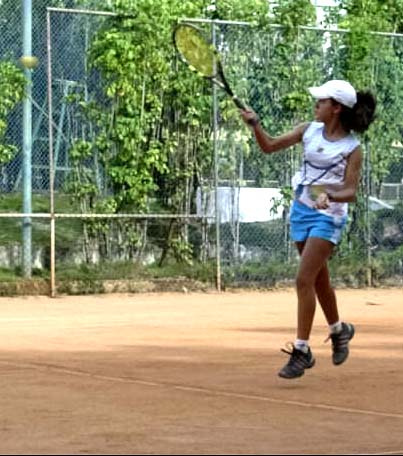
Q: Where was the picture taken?
A: At a tennis court.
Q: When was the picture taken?
A: Daytime.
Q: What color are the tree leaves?
A: Green.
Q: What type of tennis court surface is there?
A: Clay.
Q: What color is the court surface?
A: Brown.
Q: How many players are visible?
A: One.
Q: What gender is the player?
A: Female.